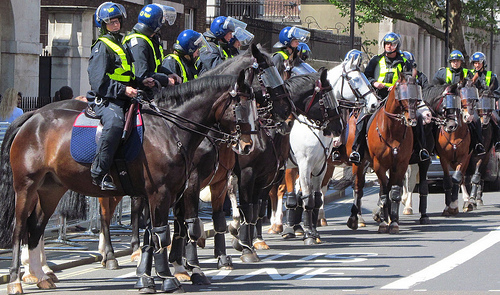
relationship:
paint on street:
[116, 245, 380, 283] [1, 165, 500, 295]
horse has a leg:
[286, 50, 380, 251] [295, 163, 314, 246]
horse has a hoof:
[286, 50, 380, 251] [303, 236, 316, 245]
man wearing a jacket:
[89, 0, 145, 191] [86, 33, 137, 101]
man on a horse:
[89, 0, 145, 191] [1, 69, 260, 294]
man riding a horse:
[89, 0, 145, 191] [1, 69, 260, 294]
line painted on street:
[372, 219, 500, 293] [1, 165, 500, 295]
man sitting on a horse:
[89, 0, 145, 191] [1, 69, 260, 294]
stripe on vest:
[124, 32, 163, 72] [121, 32, 170, 80]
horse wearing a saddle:
[1, 69, 260, 294] [68, 96, 151, 168]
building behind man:
[1, 0, 207, 132] [89, 0, 145, 191]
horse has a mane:
[1, 69, 260, 294] [147, 72, 240, 106]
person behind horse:
[2, 88, 26, 125] [1, 69, 260, 294]